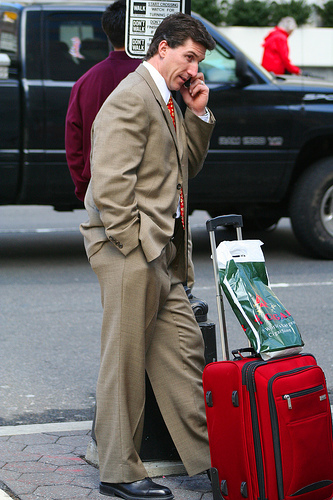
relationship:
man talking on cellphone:
[77, 12, 216, 498] [183, 75, 192, 91]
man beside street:
[77, 12, 216, 498] [0, 204, 332, 425]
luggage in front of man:
[198, 213, 332, 497] [77, 12, 216, 498]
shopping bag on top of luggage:
[209, 237, 305, 362] [198, 213, 332, 497]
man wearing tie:
[77, 12, 216, 498] [164, 94, 185, 229]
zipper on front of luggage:
[282, 392, 295, 412] [198, 213, 332, 497]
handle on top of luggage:
[205, 212, 256, 361] [198, 213, 332, 497]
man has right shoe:
[77, 12, 216, 498] [98, 475, 175, 499]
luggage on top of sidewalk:
[198, 213, 332, 497] [1, 423, 215, 499]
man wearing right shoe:
[77, 12, 216, 498] [98, 475, 175, 499]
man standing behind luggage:
[77, 12, 216, 498] [198, 213, 332, 497]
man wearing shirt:
[61, 0, 195, 298] [64, 49, 142, 204]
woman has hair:
[259, 16, 303, 74] [274, 14, 297, 37]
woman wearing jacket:
[259, 16, 303, 74] [259, 25, 299, 75]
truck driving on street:
[1, 2, 332, 263] [0, 204, 332, 425]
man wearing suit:
[77, 12, 216, 498] [79, 65, 215, 485]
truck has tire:
[1, 2, 332, 263] [288, 152, 332, 262]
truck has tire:
[1, 2, 332, 263] [202, 206, 282, 230]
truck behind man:
[1, 2, 332, 263] [77, 12, 216, 498]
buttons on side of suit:
[106, 230, 124, 253] [79, 65, 215, 485]